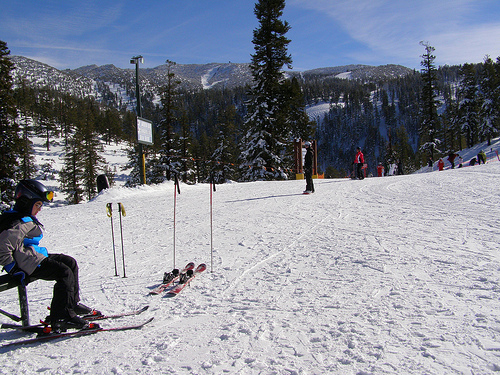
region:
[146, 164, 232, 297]
flag post for skiiers to ski thru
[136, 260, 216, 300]
a pair of skis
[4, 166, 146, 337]
a skier sitting down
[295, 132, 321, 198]
a skier standing up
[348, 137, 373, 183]
woman standing in a red jacket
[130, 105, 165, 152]
billboard with an advertisement on it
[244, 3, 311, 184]
a very tall tree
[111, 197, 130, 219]
a yellow flag post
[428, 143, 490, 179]
a group of people just hanging around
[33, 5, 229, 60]
a clear blue sky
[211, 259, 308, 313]
a section of snow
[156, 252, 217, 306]
the right unused ski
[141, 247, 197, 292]
the left unused ski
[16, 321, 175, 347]
the right ski in use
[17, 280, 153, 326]
the left ski in use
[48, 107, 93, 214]
a tall skinny tree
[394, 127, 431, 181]
a short fat tree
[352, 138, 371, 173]
a red snow jacket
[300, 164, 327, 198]
small black snow pants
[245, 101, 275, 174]
snow on a tree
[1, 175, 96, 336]
a kid looking down on the ground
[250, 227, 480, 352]
white snow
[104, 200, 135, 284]
ice skiing stilts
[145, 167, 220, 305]
a persons snow skiing equipment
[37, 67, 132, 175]
trees covered in snow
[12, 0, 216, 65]
the blue sky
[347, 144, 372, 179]
a person wearing a red ski outfit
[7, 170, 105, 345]
a child in a ski outfit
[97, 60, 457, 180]
snowy landscape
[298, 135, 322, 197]
an individual in a black outfit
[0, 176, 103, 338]
young skier sitting on a bench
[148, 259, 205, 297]
a pair of skis on the ground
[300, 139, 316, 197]
a person dressed in black standing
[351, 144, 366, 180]
a person in a red jacket standing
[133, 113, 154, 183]
a sign on a pole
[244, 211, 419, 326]
patch of ground covered with snow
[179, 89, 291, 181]
evergreens in the background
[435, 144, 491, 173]
skiers in the background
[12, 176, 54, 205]
black skiing helmet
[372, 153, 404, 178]
a group of people in the background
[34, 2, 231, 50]
a bright blue sky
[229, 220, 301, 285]
a track left on a sky trail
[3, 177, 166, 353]
a boy putting on his skis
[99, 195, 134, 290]
a pair of sky poles stuck into the snow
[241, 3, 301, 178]
a tall pine tree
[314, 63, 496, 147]
a snow covered mountain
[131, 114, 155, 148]
a sign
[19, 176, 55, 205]
a boy's helmet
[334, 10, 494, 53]
fluffy white clouds